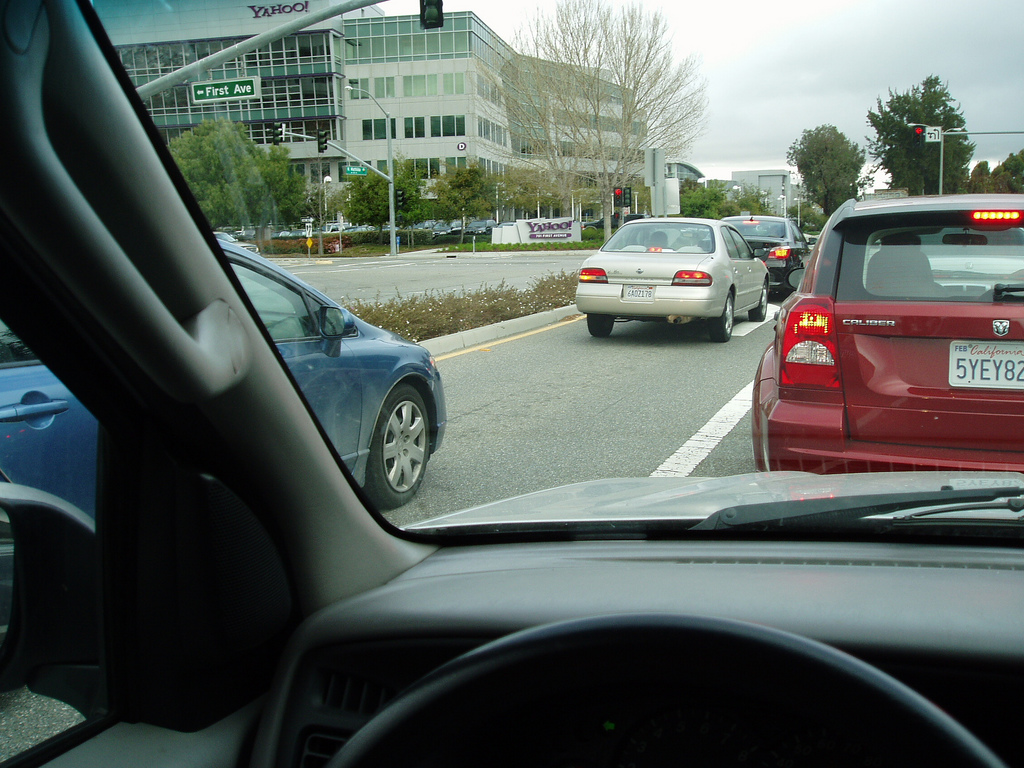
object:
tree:
[862, 67, 978, 202]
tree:
[427, 165, 495, 244]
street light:
[392, 185, 410, 212]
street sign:
[191, 77, 262, 104]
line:
[429, 311, 588, 363]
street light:
[902, 119, 919, 133]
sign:
[522, 216, 576, 241]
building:
[336, 1, 665, 259]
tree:
[781, 118, 876, 229]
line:
[649, 383, 751, 476]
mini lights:
[972, 207, 1021, 224]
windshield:
[837, 217, 1024, 306]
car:
[740, 180, 1023, 491]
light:
[413, 0, 449, 33]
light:
[912, 122, 927, 137]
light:
[613, 185, 624, 207]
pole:
[935, 128, 948, 195]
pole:
[129, 0, 391, 94]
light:
[316, 126, 331, 155]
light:
[270, 118, 286, 147]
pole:
[387, 180, 399, 257]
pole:
[619, 189, 626, 225]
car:
[722, 211, 818, 302]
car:
[0, 228, 454, 617]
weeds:
[403, 289, 504, 330]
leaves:
[689, 196, 713, 210]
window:
[359, 115, 399, 143]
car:
[569, 213, 777, 350]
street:
[495, 336, 754, 482]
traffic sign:
[922, 125, 945, 145]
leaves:
[813, 139, 844, 162]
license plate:
[937, 332, 1024, 399]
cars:
[743, 193, 1024, 484]